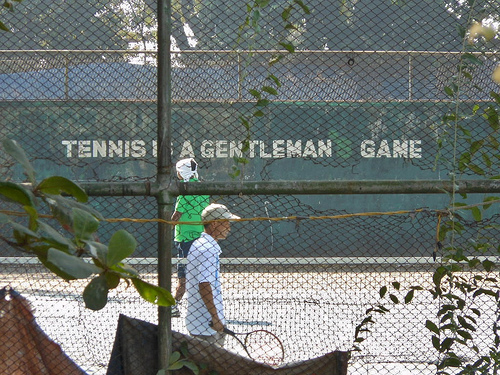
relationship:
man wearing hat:
[182, 197, 239, 347] [199, 201, 239, 235]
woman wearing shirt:
[173, 150, 212, 319] [173, 183, 208, 237]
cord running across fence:
[5, 205, 497, 233] [3, 3, 499, 374]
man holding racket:
[182, 197, 239, 347] [204, 317, 286, 374]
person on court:
[172, 153, 209, 322] [0, 254, 498, 372]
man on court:
[182, 197, 239, 347] [0, 254, 498, 372]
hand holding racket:
[212, 318, 225, 335] [208, 321, 284, 368]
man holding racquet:
[182, 197, 239, 347] [206, 318, 287, 367]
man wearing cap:
[182, 197, 239, 347] [198, 200, 242, 224]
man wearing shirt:
[182, 197, 239, 347] [184, 233, 224, 333]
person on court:
[185, 194, 235, 348] [0, 254, 498, 372]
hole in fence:
[244, 143, 498, 224] [3, 3, 499, 374]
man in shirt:
[182, 197, 239, 347] [182, 231, 230, 335]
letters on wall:
[61, 136, 424, 165] [0, 98, 497, 252]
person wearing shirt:
[171, 153, 206, 322] [172, 176, 211, 242]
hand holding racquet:
[212, 318, 225, 335] [206, 318, 287, 367]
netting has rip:
[2, 4, 497, 371] [241, 152, 499, 221]